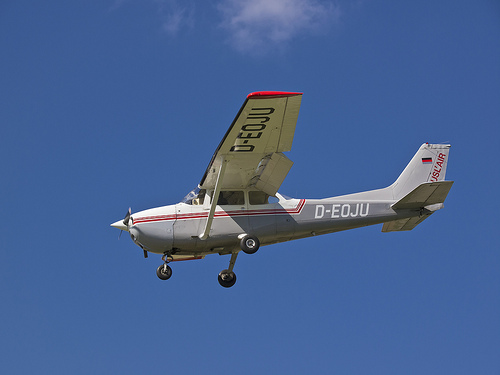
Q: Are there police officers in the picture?
A: No, there are no police officers.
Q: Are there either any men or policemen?
A: No, there are no policemen or men.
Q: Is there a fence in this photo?
A: No, there are no fences.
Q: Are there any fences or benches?
A: No, there are no fences or benches.